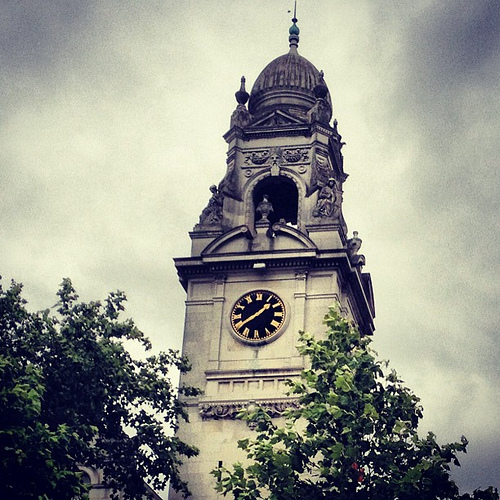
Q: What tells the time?
A: Clock.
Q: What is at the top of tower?
A: Steeple.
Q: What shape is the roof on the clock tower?
A: Dome.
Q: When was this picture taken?
A: 1:40.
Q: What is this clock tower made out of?
A: Stone.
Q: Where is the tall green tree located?
A: In front of the tower.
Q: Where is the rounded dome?
A: On top of the clock tower.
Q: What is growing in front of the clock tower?
A: A tree.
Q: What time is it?
A: 1:40.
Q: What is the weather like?
A: Stormy.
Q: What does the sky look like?
A: Cloudy.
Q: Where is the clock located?
A: Tower.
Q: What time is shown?
A: 1:40.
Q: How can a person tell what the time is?
A: Clock.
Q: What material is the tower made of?
A: Stone.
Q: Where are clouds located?
A: Sky.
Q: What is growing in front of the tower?
A: Trees.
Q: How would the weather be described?
A: Cloudy.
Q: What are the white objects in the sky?
A: Clouds.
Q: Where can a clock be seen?
A: Tower.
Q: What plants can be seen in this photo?
A: Trees.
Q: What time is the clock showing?
A: 1:40.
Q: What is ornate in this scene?
A: The clock tower.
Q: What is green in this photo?
A: Tree leaves.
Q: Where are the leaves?
A: Growing on the trees.